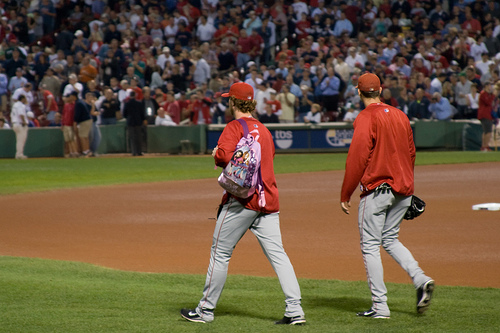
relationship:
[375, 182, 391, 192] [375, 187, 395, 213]
glove on back pocket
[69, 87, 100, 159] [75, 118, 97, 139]
man on shorts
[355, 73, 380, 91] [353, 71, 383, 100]
baseball cap on head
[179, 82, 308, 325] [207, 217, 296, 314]
baseball player on pants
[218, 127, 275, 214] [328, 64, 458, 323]
backpack on man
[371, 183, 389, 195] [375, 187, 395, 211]
glove on back pocket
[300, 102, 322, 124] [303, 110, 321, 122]
boy on shirt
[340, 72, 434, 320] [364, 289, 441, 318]
baseball player has feet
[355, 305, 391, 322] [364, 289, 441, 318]
shoe has feet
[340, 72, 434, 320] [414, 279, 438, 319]
baseball player wearing cleats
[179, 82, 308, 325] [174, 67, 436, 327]
baseball player has uniforms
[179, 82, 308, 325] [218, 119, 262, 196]
baseball player has backpack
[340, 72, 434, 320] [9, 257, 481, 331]
baseball player walking across grass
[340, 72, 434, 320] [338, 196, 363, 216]
baseball player has hand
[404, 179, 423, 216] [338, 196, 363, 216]
glove in hand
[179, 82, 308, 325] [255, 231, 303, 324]
baseball player has leg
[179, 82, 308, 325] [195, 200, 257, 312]
baseball player has leg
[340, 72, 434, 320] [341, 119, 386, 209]
baseball player has arm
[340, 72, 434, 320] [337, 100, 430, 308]
baseball player wearing uniform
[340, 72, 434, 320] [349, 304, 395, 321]
baseball player wearing shoe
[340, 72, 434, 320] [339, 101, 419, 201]
baseball player wearing jacket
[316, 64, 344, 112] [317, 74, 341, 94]
man in shirt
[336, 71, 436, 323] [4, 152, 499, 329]
baseball player walking on field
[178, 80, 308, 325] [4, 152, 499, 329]
baseball player walking on field